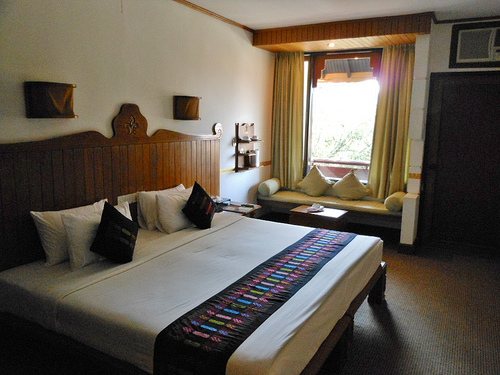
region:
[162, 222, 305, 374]
this is a bed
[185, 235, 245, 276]
the sheet is white in color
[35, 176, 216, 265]
pillows are on the bed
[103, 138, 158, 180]
the bed is wooden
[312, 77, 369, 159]
the window is open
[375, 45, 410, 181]
this is a curtain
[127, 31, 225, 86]
the wall is white in color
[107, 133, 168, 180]
the bed is brown in color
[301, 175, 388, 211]
this is a sofa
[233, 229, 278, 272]
the bed is empty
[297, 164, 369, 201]
two pillows that are propped up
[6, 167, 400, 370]
neatly made bed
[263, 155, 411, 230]
bench by the window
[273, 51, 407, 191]
curtains that have been pushed back to expose the window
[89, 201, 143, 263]
black throw pillow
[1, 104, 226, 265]
large wooden headboard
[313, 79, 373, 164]
light streaming in the through the window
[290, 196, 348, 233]
small table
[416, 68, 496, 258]
dark brown door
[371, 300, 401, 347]
shadow on the carpet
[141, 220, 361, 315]
this is a bed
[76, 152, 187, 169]
the bed is wooden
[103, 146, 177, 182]
the bed is brown in color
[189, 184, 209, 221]
this is a pillow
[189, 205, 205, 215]
the pillow is black in color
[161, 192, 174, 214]
the pillow is white in color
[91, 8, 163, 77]
this is a wall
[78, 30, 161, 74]
the wall is white in color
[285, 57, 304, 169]
this is a curtain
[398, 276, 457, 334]
this is the floor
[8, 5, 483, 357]
Hotel room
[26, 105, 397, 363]
King size bed in the bedroom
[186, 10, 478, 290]
Sitting area by the window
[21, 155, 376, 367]
White bedsheets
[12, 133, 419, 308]
White and black pillows on the bed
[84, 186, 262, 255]
Black decorative pillows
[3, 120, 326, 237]
Wooden head board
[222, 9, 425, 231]
Cream curtains on the window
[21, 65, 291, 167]
Lights above headboard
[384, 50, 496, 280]
Closet in the room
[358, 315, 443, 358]
shadow cast on the ground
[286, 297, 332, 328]
small wrinkle on bed sheet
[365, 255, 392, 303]
legs on wooden bed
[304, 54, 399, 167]
sunlight coming in the window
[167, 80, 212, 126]
brown object on wall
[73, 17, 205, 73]
white color on the wall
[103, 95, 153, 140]
decorative edge on wooden bed head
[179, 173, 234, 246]
brown pillow on bed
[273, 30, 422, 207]
yellow drapes on window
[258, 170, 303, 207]
small divan on sofa